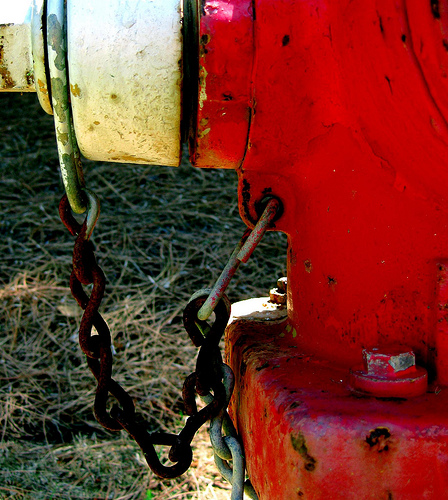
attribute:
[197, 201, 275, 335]
hook — metal, flecked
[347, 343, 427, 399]
nut — red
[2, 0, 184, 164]
arm — white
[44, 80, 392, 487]
chain/hydrant — metal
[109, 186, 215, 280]
grass — brown, dead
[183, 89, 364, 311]
hydrant — chipped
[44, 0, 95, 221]
ring — metal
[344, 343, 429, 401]
cap — red